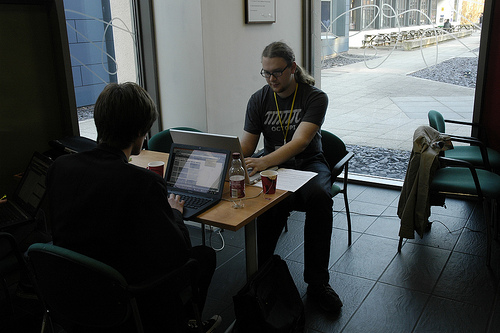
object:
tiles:
[341, 183, 499, 331]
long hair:
[260, 39, 316, 86]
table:
[128, 149, 317, 333]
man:
[41, 81, 220, 332]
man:
[240, 41, 344, 312]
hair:
[93, 82, 159, 151]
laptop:
[164, 142, 232, 221]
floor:
[183, 180, 498, 333]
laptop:
[168, 128, 280, 186]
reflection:
[173, 150, 225, 194]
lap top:
[164, 142, 232, 221]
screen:
[166, 148, 227, 195]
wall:
[152, 1, 303, 154]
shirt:
[243, 84, 329, 167]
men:
[49, 42, 343, 333]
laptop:
[162, 128, 278, 221]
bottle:
[228, 152, 246, 209]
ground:
[350, 67, 430, 181]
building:
[62, 0, 144, 142]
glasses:
[259, 65, 290, 78]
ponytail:
[295, 63, 316, 86]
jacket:
[396, 124, 455, 240]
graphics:
[316, 0, 483, 148]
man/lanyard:
[240, 40, 329, 177]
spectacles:
[260, 65, 289, 78]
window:
[304, 0, 488, 181]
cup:
[260, 170, 279, 194]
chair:
[397, 110, 500, 255]